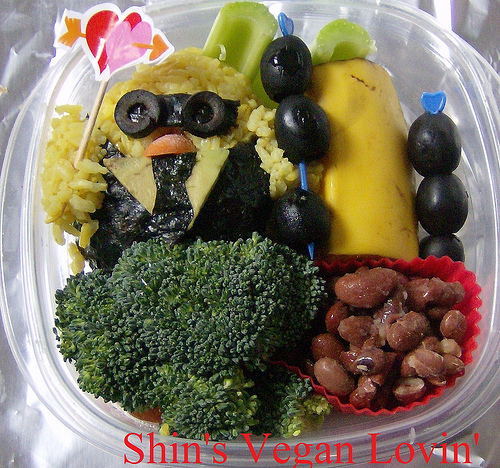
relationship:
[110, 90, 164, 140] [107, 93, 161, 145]
slice of olive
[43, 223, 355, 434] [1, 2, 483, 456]
broccoli on dish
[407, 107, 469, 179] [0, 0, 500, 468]
olive in bowl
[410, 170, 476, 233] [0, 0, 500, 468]
olive in bowl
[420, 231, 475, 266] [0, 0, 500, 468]
olive in bowl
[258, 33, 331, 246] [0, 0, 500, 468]
black olives in bowl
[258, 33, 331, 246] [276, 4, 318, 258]
black olives on toothpicks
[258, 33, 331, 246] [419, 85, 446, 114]
black olives on toothpicks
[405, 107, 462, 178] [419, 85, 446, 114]
olive on toothpicks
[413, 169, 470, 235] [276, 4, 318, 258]
olive on toothpicks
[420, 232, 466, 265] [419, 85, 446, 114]
olive on toothpicks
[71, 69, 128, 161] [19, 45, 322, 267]
toothpick in hand of bird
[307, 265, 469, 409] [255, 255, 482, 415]
beans in cup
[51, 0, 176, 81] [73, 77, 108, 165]
sticker on toothpick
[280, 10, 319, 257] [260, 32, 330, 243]
blue toothpick with black olives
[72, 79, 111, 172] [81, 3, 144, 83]
toothpick with heart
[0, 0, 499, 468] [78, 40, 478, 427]
dish full of food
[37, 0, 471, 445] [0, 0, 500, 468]
food in bowl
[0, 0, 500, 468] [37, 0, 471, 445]
bowl holding food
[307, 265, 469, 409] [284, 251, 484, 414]
beans in cup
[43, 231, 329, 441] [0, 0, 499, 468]
broccoli on dish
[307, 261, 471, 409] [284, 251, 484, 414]
beans in cup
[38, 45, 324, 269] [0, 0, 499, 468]
rice on dish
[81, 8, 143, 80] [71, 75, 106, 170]
heart on stick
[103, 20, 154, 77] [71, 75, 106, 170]
heart on stick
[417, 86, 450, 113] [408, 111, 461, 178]
heart stuck in olive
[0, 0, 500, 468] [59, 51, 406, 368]
bowl packed with food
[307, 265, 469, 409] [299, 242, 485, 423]
beans in cup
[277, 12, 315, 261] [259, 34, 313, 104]
blue toothpick holding olive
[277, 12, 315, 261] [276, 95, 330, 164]
blue toothpick holding olive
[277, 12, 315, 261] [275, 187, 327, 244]
blue toothpick holding olive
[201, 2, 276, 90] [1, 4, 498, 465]
celery in bowl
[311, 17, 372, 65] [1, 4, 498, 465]
celery in bowl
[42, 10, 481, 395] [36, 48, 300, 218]
food on rice